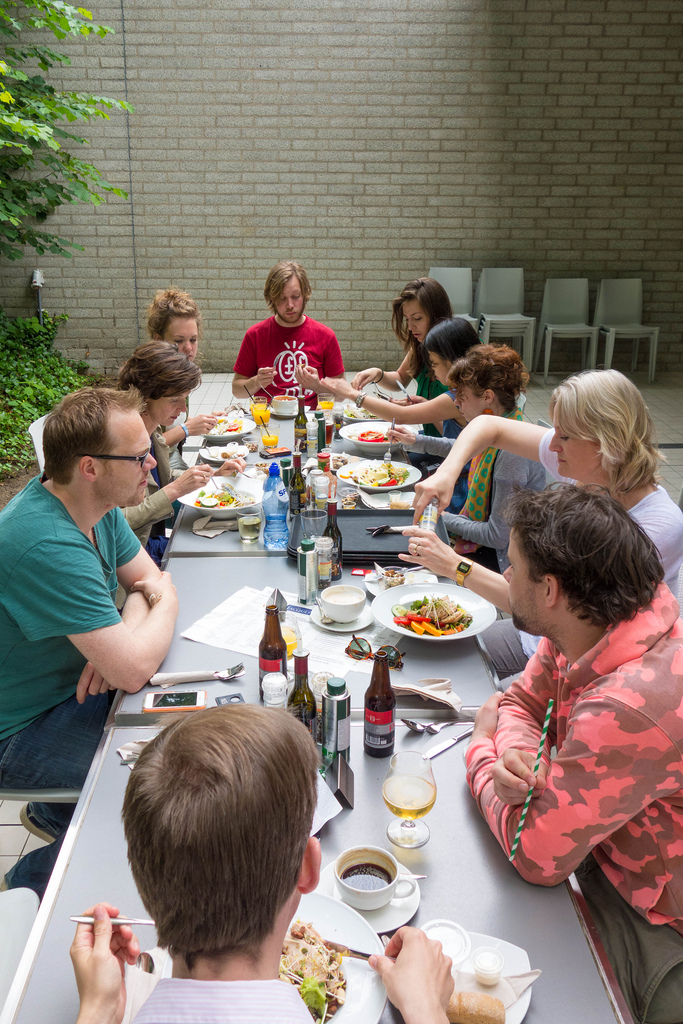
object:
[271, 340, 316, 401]
writing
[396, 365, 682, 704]
woman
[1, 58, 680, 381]
wall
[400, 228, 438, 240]
brick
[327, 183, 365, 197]
brick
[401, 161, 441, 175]
brick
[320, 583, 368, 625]
bowl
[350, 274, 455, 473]
lady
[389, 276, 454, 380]
hair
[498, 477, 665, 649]
head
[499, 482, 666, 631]
hair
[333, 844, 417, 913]
cup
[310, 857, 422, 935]
saucer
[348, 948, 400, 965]
knife handle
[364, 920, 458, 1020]
hand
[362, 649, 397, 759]
bottle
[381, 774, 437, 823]
liquid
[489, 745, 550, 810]
hand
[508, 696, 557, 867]
straw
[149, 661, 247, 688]
utensils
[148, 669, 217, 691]
napkin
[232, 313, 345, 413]
shirt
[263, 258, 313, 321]
hair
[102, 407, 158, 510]
face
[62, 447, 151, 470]
glasses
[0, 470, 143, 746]
shirt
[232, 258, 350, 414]
man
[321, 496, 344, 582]
bottle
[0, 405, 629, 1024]
table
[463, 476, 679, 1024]
man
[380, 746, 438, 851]
glass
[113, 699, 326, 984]
head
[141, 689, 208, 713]
phone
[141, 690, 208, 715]
case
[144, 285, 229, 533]
lady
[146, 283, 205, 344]
hair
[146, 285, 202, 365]
head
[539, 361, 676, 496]
hair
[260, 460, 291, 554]
bottle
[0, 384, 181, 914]
gentleman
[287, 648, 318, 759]
bottle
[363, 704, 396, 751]
label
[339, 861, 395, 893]
coffee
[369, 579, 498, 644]
plate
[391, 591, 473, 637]
dish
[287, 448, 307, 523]
bottle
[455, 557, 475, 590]
watch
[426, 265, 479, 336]
chairs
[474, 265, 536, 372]
chairs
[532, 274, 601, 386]
chairs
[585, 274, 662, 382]
chairs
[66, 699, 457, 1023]
guy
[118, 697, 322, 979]
hair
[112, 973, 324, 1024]
shirt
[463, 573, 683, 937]
hoodie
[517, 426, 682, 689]
t-shirt